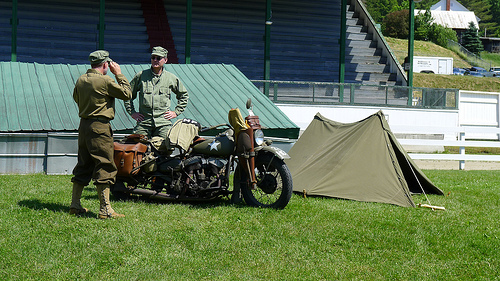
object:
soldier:
[69, 49, 134, 220]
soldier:
[123, 45, 190, 139]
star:
[207, 139, 219, 151]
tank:
[190, 135, 236, 155]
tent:
[275, 108, 445, 211]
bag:
[112, 140, 151, 176]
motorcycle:
[106, 97, 292, 212]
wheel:
[238, 149, 293, 211]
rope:
[384, 114, 436, 211]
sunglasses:
[150, 55, 165, 61]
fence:
[389, 124, 500, 169]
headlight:
[251, 127, 265, 146]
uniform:
[125, 67, 188, 140]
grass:
[1, 167, 499, 280]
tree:
[459, 21, 484, 57]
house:
[413, 2, 484, 48]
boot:
[68, 181, 93, 215]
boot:
[98, 185, 125, 221]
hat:
[150, 45, 169, 59]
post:
[11, 1, 19, 61]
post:
[99, 1, 107, 49]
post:
[184, 1, 193, 63]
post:
[262, 0, 272, 100]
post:
[336, 1, 348, 102]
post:
[407, 1, 415, 105]